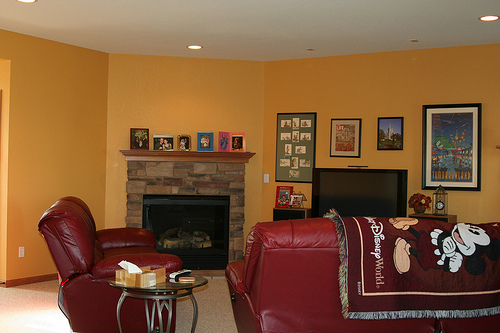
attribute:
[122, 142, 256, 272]
fireplace — brown, stone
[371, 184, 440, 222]
flowers — small, red, white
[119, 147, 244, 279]
firepace — brick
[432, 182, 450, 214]
birdcage — clock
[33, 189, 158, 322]
chair — red, leather, soft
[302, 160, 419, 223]
television — black